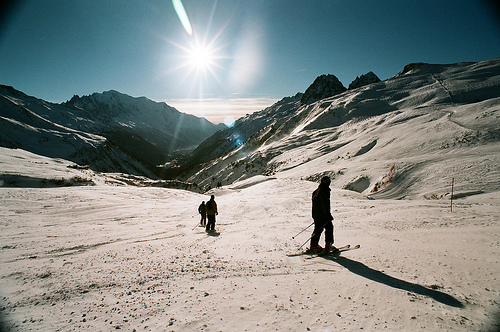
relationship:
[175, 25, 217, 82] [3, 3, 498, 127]
sun in sky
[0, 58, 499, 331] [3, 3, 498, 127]
mountains below sky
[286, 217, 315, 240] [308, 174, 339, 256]
left ski pole of skier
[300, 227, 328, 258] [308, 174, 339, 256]
right ski pole of skier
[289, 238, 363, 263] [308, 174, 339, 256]
skis of skier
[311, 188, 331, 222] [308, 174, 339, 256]
jacket of skier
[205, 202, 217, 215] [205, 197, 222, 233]
jacket of skier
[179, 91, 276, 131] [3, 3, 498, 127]
clouds in sky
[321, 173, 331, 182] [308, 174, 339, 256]
hat of skier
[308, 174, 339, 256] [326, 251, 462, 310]
skier casting a shadow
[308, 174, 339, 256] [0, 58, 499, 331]
skier on mountains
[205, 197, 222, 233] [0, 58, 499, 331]
skier on mountains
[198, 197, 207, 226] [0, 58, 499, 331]
person on mountains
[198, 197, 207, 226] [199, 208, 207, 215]
person wearing a coat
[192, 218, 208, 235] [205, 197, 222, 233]
pole of skier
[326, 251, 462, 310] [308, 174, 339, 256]
shadow of skier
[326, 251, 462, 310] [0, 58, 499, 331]
shadow on mountains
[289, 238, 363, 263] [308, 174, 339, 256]
skis on skier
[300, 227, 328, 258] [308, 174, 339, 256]
right ski pole used by skier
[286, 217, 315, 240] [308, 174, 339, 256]
left ski pole used by skier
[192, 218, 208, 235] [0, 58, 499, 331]
pole on mountains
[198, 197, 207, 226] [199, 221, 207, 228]
person on skis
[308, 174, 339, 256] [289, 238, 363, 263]
skier on skis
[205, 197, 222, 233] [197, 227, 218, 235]
skier on skis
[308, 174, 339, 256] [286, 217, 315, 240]
skier holding left ski pole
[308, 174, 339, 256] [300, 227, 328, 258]
skier holding right ski pole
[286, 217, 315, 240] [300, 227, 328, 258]
left ski pole and right ski pole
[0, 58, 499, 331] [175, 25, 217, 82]
mountains under sun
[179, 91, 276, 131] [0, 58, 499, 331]
clouds between mountains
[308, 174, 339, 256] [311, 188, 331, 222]
skier in jacket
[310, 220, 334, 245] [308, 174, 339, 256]
pants of skier